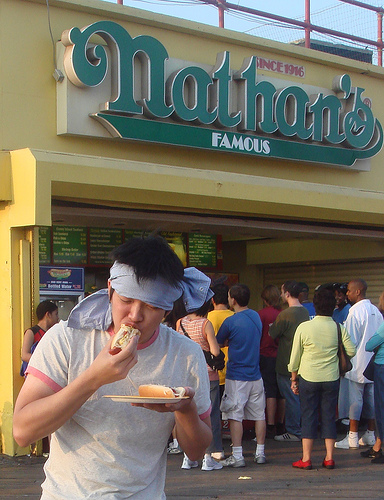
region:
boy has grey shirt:
[40, 326, 204, 473]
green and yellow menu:
[43, 228, 236, 277]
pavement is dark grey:
[231, 453, 279, 497]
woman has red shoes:
[287, 450, 350, 475]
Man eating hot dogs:
[12, 234, 217, 498]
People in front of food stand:
[26, 274, 382, 469]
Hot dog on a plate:
[104, 382, 188, 405]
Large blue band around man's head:
[65, 262, 213, 330]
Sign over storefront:
[54, 17, 382, 171]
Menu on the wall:
[34, 220, 223, 270]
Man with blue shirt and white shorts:
[217, 280, 265, 468]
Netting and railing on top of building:
[117, 0, 383, 54]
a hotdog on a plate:
[129, 366, 175, 406]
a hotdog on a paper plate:
[137, 373, 198, 434]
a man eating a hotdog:
[105, 306, 134, 350]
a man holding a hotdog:
[97, 317, 139, 355]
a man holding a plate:
[148, 363, 250, 448]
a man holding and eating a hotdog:
[82, 301, 160, 393]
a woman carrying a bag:
[301, 282, 370, 464]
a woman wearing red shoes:
[282, 306, 347, 498]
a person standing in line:
[200, 283, 310, 463]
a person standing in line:
[293, 266, 334, 443]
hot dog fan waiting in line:
[283, 284, 352, 470]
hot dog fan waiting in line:
[336, 277, 383, 449]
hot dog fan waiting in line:
[268, 281, 311, 445]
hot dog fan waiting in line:
[331, 279, 345, 309]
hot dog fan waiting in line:
[214, 283, 271, 462]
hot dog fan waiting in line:
[19, 298, 62, 372]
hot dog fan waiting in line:
[257, 283, 282, 434]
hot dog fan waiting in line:
[292, 278, 314, 318]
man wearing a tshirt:
[8, 243, 213, 491]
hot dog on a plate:
[133, 378, 182, 398]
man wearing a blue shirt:
[223, 279, 269, 468]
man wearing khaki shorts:
[217, 285, 267, 466]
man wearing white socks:
[223, 284, 271, 465]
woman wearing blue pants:
[277, 278, 345, 489]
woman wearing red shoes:
[288, 278, 348, 484]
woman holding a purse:
[290, 284, 359, 472]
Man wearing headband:
[45, 231, 262, 367]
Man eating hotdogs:
[87, 304, 207, 437]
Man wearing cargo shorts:
[205, 267, 278, 485]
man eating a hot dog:
[12, 235, 210, 498]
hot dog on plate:
[102, 381, 190, 405]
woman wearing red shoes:
[286, 287, 355, 468]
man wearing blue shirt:
[217, 284, 269, 467]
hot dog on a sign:
[40, 266, 81, 288]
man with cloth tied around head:
[13, 237, 210, 498]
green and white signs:
[38, 224, 217, 267]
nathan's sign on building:
[2, 2, 380, 455]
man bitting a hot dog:
[12, 237, 216, 498]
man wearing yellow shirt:
[204, 283, 234, 399]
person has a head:
[108, 238, 184, 341]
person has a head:
[226, 283, 251, 309]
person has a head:
[193, 299, 212, 316]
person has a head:
[210, 282, 229, 303]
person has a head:
[261, 283, 280, 304]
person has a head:
[313, 287, 335, 313]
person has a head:
[345, 278, 368, 299]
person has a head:
[335, 283, 346, 305]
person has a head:
[37, 299, 58, 326]